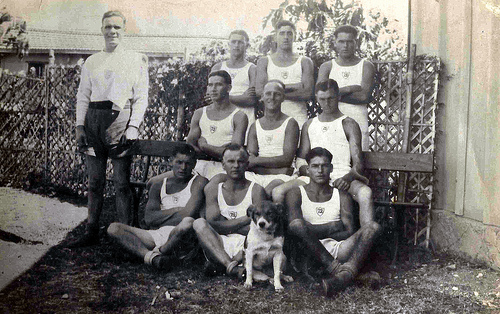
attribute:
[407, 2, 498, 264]
wall — old, grey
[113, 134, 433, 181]
wooden plank — gray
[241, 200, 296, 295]
dog — in picture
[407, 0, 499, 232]
wall — in picture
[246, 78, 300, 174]
young man — gray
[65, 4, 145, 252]
coach — in picture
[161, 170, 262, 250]
tops — in picture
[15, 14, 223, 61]
roof — in picture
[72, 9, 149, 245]
coach — in picture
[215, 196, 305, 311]
dog — sitting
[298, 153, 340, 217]
member — men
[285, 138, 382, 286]
man — in picture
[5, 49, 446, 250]
fence — metal, in picture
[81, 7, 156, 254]
man — sitting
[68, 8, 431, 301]
group — gray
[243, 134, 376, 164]
floor — in picture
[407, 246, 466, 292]
ground — gray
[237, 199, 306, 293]
dog — sitting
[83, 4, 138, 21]
hair — straight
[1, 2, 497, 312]
picture — straight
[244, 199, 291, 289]
dog — in picture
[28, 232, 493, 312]
grass — short